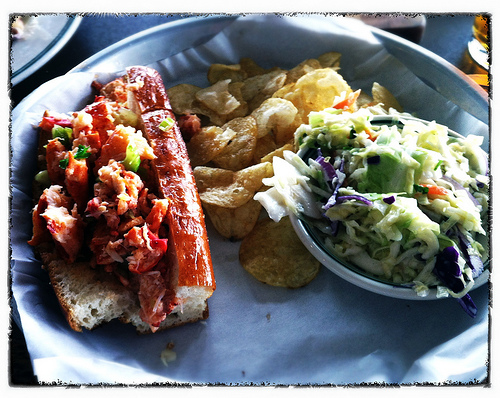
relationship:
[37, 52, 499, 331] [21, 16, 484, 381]
food on top of plate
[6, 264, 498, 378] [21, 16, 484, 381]
napkin on plate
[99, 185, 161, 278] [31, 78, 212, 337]
meat inside bun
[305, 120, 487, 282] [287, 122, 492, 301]
salad in bowl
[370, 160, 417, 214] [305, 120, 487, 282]
lettuce mixed in salad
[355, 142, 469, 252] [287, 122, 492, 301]
coleslaw in bowl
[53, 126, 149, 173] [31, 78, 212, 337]
vegetables in bun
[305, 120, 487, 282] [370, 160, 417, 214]
salad has lettuce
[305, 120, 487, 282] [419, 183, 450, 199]
salad has carrot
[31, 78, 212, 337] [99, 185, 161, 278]
bun has meat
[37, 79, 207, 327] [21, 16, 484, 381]
sandwich on plate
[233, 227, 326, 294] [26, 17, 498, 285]
potato chip on top of table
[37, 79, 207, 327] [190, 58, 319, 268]
sandwich next to potato chips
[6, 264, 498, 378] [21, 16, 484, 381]
napkin covering plate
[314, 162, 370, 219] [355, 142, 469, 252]
cabbage in coleslaw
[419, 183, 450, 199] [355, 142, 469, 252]
carrot in coleslaw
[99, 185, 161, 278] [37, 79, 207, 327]
meat inside sandwich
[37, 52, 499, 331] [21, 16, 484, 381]
food on plate